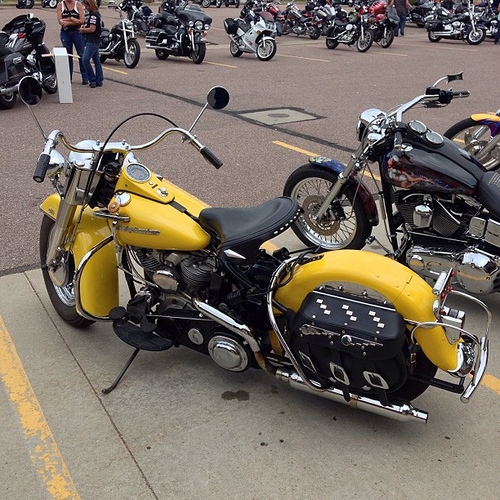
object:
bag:
[291, 288, 407, 397]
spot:
[218, 388, 253, 402]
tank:
[107, 161, 213, 252]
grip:
[33, 153, 52, 183]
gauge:
[126, 162, 152, 183]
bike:
[223, 11, 278, 61]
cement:
[233, 105, 325, 126]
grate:
[268, 112, 290, 118]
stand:
[101, 346, 141, 394]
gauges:
[409, 119, 444, 145]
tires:
[229, 40, 243, 58]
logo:
[115, 224, 159, 237]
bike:
[18, 73, 490, 425]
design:
[384, 151, 473, 196]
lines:
[71, 57, 129, 75]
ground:
[0, 0, 500, 500]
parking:
[0, 0, 497, 500]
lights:
[439, 268, 452, 306]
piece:
[427, 260, 473, 345]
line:
[0, 314, 79, 500]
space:
[5, 280, 362, 497]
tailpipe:
[274, 368, 429, 426]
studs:
[273, 208, 300, 235]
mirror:
[204, 85, 233, 110]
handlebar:
[131, 126, 225, 170]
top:
[268, 112, 289, 118]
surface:
[238, 96, 321, 127]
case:
[290, 285, 407, 398]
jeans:
[82, 40, 103, 87]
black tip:
[200, 146, 224, 169]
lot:
[0, 0, 500, 425]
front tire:
[39, 213, 96, 330]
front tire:
[283, 161, 372, 254]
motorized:
[238, 43, 255, 53]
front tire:
[256, 40, 278, 62]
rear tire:
[391, 353, 440, 406]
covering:
[238, 105, 323, 127]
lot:
[253, 100, 346, 180]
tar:
[233, 111, 283, 134]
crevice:
[237, 125, 305, 183]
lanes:
[0, 195, 492, 500]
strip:
[0, 322, 78, 500]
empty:
[288, 54, 324, 80]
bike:
[282, 72, 500, 298]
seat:
[198, 196, 303, 252]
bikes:
[0, 9, 59, 110]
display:
[17, 77, 491, 425]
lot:
[12, 399, 180, 499]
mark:
[0, 311, 78, 500]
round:
[206, 86, 230, 112]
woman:
[78, 1, 105, 89]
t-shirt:
[86, 10, 102, 43]